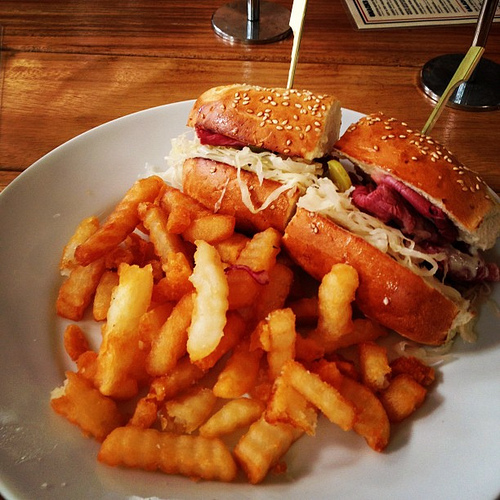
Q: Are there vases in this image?
A: No, there are no vases.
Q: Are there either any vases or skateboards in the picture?
A: No, there are no vases or skateboards.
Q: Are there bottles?
A: No, there are no bottles.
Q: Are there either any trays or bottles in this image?
A: No, there are no bottles or trays.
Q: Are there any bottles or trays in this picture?
A: No, there are no bottles or trays.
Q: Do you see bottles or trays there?
A: No, there are no bottles or trays.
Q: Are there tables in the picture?
A: Yes, there is a table.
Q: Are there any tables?
A: Yes, there is a table.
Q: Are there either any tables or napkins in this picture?
A: Yes, there is a table.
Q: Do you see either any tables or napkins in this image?
A: Yes, there is a table.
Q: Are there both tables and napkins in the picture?
A: No, there is a table but no napkins.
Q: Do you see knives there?
A: No, there are no knives.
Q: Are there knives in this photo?
A: No, there are no knives.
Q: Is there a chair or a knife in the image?
A: No, there are no knives or chairs.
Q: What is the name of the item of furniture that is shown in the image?
A: The piece of furniture is a table.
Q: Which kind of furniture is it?
A: The piece of furniture is a table.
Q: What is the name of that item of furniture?
A: This is a table.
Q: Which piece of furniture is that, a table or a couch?
A: This is a table.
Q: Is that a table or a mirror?
A: That is a table.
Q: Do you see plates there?
A: Yes, there is a plate.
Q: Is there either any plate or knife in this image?
A: Yes, there is a plate.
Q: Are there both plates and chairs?
A: No, there is a plate but no chairs.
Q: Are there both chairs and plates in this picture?
A: No, there is a plate but no chairs.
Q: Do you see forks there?
A: No, there are no forks.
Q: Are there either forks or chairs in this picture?
A: No, there are no forks or chairs.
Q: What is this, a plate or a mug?
A: This is a plate.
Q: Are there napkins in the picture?
A: No, there are no napkins.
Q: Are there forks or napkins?
A: No, there are no napkins or forks.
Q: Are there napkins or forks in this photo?
A: No, there are no napkins or forks.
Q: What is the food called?
A: The food is fries.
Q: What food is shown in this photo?
A: The food is fries.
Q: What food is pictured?
A: The food is fries.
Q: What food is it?
A: The food is fries.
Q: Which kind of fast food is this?
A: These are fries.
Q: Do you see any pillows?
A: No, there are no pillows.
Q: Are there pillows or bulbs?
A: No, there are no pillows or bulbs.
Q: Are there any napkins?
A: No, there are no napkins.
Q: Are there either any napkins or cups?
A: No, there are no napkins or cups.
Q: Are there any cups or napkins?
A: No, there are no napkins or cups.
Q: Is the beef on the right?
A: Yes, the beef is on the right of the image.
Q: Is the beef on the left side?
A: No, the beef is on the right of the image.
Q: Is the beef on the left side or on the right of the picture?
A: The beef is on the right of the image.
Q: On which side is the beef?
A: The beef is on the right of the image.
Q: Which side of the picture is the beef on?
A: The beef is on the right of the image.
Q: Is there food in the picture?
A: Yes, there is food.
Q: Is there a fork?
A: No, there are no forks.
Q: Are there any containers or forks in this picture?
A: No, there are no forks or containers.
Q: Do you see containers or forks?
A: No, there are no forks or containers.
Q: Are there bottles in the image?
A: No, there are no bottles.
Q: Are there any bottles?
A: No, there are no bottles.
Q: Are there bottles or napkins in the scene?
A: No, there are no bottles or napkins.